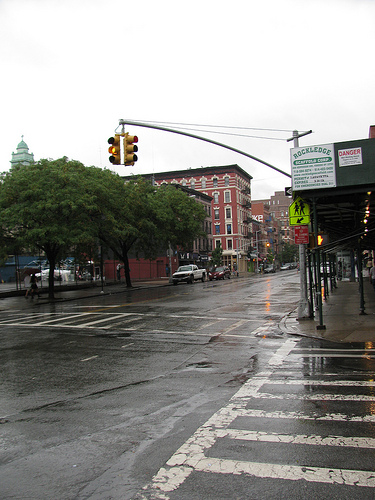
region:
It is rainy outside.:
[9, 9, 369, 499]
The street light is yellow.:
[102, 131, 143, 164]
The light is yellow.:
[107, 143, 117, 155]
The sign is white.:
[288, 142, 336, 194]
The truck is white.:
[169, 256, 206, 282]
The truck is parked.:
[165, 264, 209, 282]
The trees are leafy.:
[0, 159, 210, 263]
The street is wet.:
[8, 262, 340, 497]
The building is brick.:
[139, 170, 263, 263]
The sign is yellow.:
[281, 194, 314, 224]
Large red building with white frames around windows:
[88, 162, 255, 283]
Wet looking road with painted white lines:
[0, 266, 374, 498]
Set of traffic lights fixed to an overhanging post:
[107, 116, 314, 321]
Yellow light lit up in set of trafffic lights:
[107, 144, 120, 154]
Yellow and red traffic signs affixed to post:
[286, 193, 312, 247]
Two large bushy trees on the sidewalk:
[0, 157, 208, 300]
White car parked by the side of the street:
[170, 263, 208, 284]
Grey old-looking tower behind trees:
[9, 132, 35, 174]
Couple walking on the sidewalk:
[22, 270, 42, 301]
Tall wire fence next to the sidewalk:
[0, 226, 174, 296]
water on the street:
[232, 287, 289, 319]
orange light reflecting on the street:
[257, 271, 275, 307]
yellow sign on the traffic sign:
[313, 230, 332, 257]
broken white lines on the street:
[165, 446, 287, 480]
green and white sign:
[270, 128, 350, 206]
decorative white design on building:
[173, 164, 238, 194]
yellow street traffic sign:
[94, 113, 159, 178]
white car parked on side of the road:
[163, 255, 221, 291]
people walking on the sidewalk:
[17, 262, 58, 297]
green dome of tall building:
[6, 127, 47, 160]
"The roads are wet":
[0, 293, 374, 493]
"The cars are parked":
[160, 259, 251, 289]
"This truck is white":
[166, 257, 212, 286]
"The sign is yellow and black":
[275, 194, 320, 226]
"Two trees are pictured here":
[0, 154, 229, 310]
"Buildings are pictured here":
[0, 121, 374, 320]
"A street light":
[92, 121, 144, 170]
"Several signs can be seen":
[280, 133, 374, 280]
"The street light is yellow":
[89, 116, 169, 173]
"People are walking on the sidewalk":
[3, 251, 142, 304]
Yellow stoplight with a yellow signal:
[102, 117, 137, 167]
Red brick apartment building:
[83, 162, 248, 282]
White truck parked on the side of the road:
[165, 262, 205, 280]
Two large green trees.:
[0, 155, 210, 296]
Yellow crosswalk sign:
[285, 192, 311, 223]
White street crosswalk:
[0, 303, 291, 335]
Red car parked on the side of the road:
[205, 262, 230, 281]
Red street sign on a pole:
[291, 222, 311, 247]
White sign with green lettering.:
[288, 142, 338, 194]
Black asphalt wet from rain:
[0, 264, 373, 497]